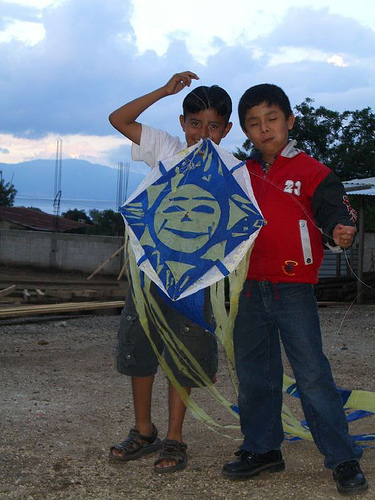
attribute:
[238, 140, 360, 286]
jacket — red, numbered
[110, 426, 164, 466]
sandal — black, brown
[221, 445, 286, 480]
shoe — black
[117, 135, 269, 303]
kite — sunny, blue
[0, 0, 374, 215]
sky — cloudy, gray, sunny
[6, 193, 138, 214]
line — behind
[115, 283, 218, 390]
shorts — dark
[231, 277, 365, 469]
jeans — blue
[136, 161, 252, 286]
sun — yellow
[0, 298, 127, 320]
plank — pink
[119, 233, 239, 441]
tail — yellow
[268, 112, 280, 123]
eye — closed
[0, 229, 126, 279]
wall — cement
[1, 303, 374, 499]
ground — gravely, brown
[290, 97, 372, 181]
tree — tall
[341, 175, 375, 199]
roof — behind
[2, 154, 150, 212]
mountain — behind